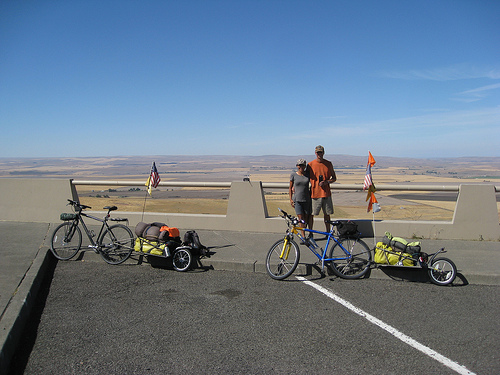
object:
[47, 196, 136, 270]
bicycle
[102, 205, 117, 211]
seat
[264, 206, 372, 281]
bicycle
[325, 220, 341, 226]
seat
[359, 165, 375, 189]
flags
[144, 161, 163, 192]
flag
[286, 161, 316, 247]
owners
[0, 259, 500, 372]
parking lot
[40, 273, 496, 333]
segments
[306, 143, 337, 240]
male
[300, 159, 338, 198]
shirt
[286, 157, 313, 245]
female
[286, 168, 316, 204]
shirt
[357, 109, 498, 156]
clouds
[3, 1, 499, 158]
sky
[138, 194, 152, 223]
stick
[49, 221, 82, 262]
tire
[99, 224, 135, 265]
tire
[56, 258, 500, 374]
pavement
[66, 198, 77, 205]
handle bars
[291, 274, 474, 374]
line